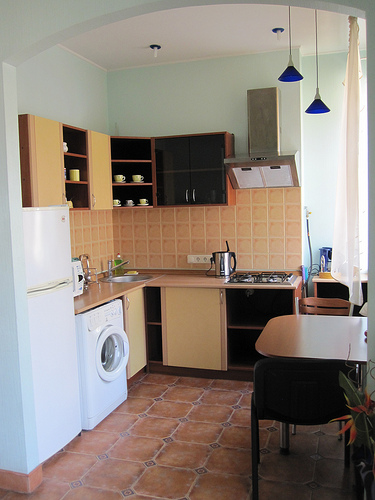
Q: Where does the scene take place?
A: In a kitchen.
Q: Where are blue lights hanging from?
A: Ceiling.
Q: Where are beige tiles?
A: On the walls.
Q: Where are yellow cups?
A: On shelves.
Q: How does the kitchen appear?
A: Neat and tidy.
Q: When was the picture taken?
A: During daytime.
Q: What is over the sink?
A: A faucet.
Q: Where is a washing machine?
A: Under the counter.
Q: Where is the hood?
A: Above the stove.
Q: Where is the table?
A: Across from the fridge.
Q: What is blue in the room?
A: The light covers.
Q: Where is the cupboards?
A: On the wall.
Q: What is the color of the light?
A: Blue.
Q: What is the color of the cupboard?
A: Brown.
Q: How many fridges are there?
A: 1.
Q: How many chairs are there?
A: 2.